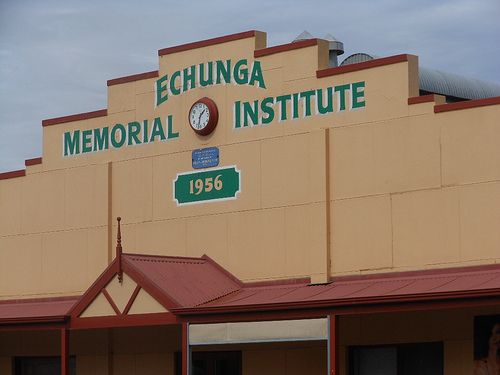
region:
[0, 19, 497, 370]
a yellow and red building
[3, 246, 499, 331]
the roof of building is red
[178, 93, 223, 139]
a clock on a wall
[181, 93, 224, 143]
clock is color white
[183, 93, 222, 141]
clock has red frame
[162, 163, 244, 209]
a green sign with number 1956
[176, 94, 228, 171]
a blue sign below a clock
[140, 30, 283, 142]
a green letter above the clock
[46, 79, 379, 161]
green letters on side the clock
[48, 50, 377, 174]
green and white letters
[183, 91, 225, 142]
The clock is red.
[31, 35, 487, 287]
The front of the building is brown.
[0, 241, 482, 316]
The roof is red.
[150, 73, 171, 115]
The letter is green.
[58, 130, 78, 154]
The letter is green.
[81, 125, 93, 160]
The letter is green.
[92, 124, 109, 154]
The letter is green.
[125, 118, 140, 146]
The letter is green.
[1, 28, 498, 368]
this is a building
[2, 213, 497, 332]
this is a rooftop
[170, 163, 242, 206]
this is a number on the buiding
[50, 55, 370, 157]
this is the name on the building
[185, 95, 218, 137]
this is a red clock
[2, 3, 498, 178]
this is the blue sky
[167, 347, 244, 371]
this is the doorway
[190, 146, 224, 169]
thats a blue sign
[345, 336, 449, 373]
this is a window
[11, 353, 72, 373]
that is a window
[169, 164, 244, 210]
the number 1956 on a wall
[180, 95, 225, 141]
a red clock on a beige building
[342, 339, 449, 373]
a window on a beige building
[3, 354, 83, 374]
a window on a beige building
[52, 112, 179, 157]
the word MEMORIAL on a beige building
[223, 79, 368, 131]
the word INSTITUTE on a beige building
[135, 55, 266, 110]
the word ECHUNGA on a beige building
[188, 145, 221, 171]
a metal plate with writing on a wall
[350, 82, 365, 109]
the letter E on a beige building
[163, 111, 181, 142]
the letter L on a beige building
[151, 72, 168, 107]
the letter E on the front of a building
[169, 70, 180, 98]
the letter C on the front of a building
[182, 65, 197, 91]
the letter H on the front of a building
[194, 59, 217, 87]
the letter U on the front of a building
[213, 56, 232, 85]
the letter N on the front of a building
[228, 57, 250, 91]
the letter G on the front of a building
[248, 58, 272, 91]
the letter A on the front of a building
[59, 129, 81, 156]
the letter M on the front of a building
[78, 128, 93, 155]
the letter E on the front of a building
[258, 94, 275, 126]
the letter S on the front of a building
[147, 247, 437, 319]
a building with a red roof